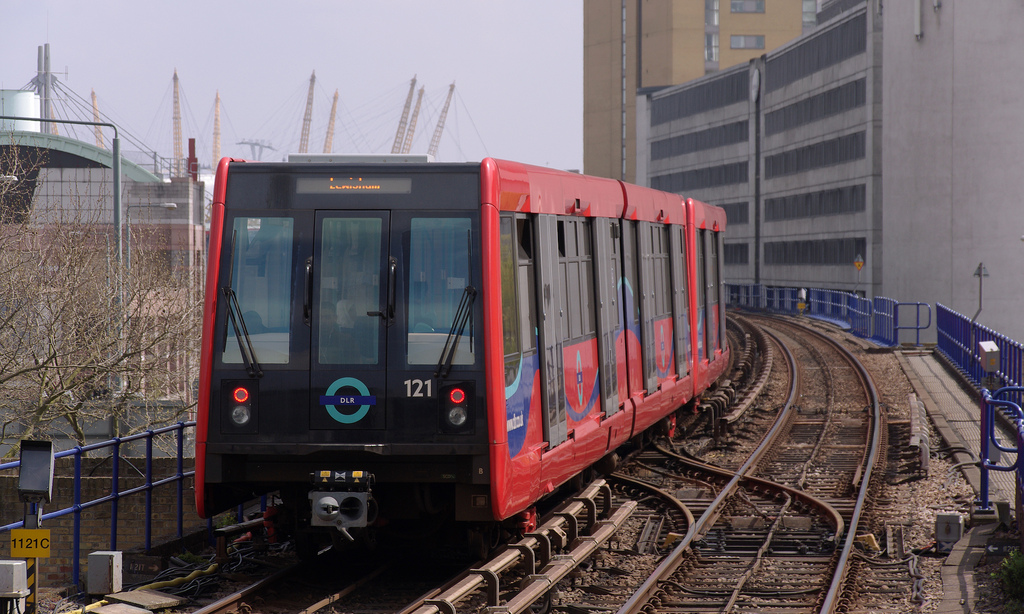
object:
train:
[193, 154, 729, 534]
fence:
[0, 419, 267, 585]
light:
[450, 388, 465, 404]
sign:
[10, 529, 51, 558]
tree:
[0, 129, 209, 458]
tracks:
[615, 310, 882, 614]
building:
[582, 0, 821, 184]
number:
[404, 379, 431, 397]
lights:
[232, 388, 468, 425]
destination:
[330, 177, 381, 189]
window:
[222, 217, 296, 364]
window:
[319, 217, 382, 365]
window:
[406, 217, 473, 365]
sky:
[0, 0, 585, 174]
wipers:
[220, 285, 478, 378]